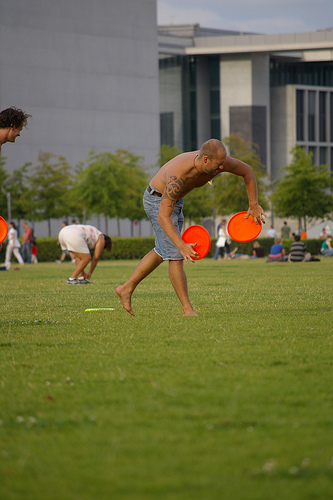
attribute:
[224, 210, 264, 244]
frisbee — being held, orange, red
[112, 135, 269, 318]
man — shirtless, standing, Bent, barefoot, without a shirt, bending over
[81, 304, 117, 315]
frisbee — green, yellow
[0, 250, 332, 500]
ground — green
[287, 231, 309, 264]
person — sitting down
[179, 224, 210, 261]
frisbee — orange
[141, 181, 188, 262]
shorts — jean, blue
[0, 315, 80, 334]
patch — small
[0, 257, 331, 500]
grass — green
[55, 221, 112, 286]
woman — bending over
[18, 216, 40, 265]
person — walking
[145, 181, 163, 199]
belt — black